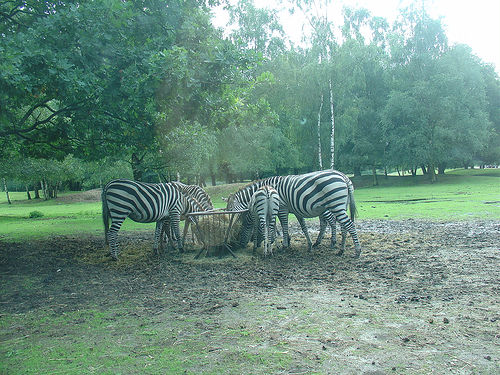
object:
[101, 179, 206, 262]
zebra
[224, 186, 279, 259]
zebra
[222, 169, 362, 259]
zebra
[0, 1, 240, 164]
leaves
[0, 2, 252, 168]
tree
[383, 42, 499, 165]
leaves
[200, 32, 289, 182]
leaves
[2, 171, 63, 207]
trees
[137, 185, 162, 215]
stripes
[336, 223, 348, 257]
back leg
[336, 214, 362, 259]
back leg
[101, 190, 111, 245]
tail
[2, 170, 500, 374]
grass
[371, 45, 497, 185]
tree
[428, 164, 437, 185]
trunk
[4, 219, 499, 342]
dirt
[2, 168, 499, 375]
ground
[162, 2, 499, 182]
trees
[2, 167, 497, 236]
green grass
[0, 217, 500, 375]
brown grass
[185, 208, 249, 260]
hay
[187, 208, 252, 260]
trough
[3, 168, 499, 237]
field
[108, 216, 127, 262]
hind legs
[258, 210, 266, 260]
hind legs